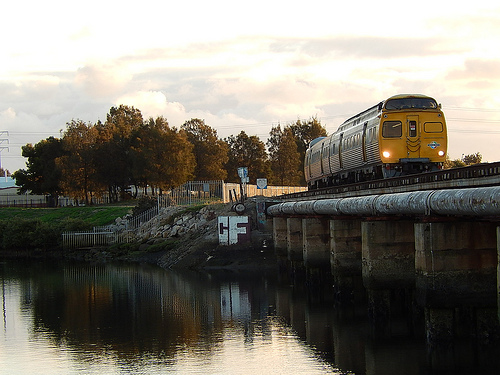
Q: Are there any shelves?
A: No, there are no shelves.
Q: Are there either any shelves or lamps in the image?
A: No, there are no shelves or lamps.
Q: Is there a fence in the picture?
A: Yes, there is a fence.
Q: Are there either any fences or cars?
A: Yes, there is a fence.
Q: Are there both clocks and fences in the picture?
A: No, there is a fence but no clocks.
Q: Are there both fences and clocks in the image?
A: No, there is a fence but no clocks.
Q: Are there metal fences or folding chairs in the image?
A: Yes, there is a metal fence.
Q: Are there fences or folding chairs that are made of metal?
A: Yes, the fence is made of metal.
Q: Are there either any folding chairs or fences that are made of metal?
A: Yes, the fence is made of metal.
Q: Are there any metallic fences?
A: Yes, there is a metal fence.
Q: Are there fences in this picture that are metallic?
A: Yes, there is a fence that is metallic.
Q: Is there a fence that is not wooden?
A: Yes, there is a metallic fence.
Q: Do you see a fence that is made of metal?
A: Yes, there is a fence that is made of metal.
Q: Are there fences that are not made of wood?
A: Yes, there is a fence that is made of metal.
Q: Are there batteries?
A: No, there are no batteries.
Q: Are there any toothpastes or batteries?
A: No, there are no batteries or toothpastes.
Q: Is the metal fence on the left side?
A: Yes, the fence is on the left of the image.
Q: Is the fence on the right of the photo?
A: No, the fence is on the left of the image.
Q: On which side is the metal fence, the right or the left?
A: The fence is on the left of the image.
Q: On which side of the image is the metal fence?
A: The fence is on the left of the image.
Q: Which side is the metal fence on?
A: The fence is on the left of the image.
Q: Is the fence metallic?
A: Yes, the fence is metallic.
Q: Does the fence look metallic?
A: Yes, the fence is metallic.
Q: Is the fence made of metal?
A: Yes, the fence is made of metal.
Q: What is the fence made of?
A: The fence is made of metal.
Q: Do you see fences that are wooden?
A: No, there is a fence but it is metallic.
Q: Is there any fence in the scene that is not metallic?
A: No, there is a fence but it is metallic.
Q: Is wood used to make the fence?
A: No, the fence is made of metal.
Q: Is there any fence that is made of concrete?
A: No, there is a fence but it is made of metal.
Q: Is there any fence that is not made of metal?
A: No, there is a fence but it is made of metal.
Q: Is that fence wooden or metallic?
A: The fence is metallic.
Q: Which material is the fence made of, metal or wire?
A: The fence is made of metal.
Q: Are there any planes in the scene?
A: No, there are no planes.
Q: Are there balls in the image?
A: No, there are no balls.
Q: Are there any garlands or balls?
A: No, there are no balls or garlands.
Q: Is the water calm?
A: Yes, the water is calm.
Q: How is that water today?
A: The water is calm.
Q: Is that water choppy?
A: No, the water is calm.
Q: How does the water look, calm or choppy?
A: The water is calm.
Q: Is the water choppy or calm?
A: The water is calm.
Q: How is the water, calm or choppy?
A: The water is calm.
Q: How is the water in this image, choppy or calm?
A: The water is calm.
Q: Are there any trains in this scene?
A: Yes, there is a train.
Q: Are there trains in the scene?
A: Yes, there is a train.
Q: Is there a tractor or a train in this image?
A: Yes, there is a train.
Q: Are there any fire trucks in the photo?
A: No, there are no fire trucks.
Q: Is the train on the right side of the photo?
A: Yes, the train is on the right of the image.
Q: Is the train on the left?
A: No, the train is on the right of the image.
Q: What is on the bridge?
A: The train is on the bridge.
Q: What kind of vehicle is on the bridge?
A: The vehicle is a train.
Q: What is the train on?
A: The train is on the bridge.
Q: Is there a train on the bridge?
A: Yes, there is a train on the bridge.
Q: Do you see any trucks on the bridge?
A: No, there is a train on the bridge.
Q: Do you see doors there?
A: Yes, there is a door.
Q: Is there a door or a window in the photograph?
A: Yes, there is a door.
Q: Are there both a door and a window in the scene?
A: Yes, there are both a door and a window.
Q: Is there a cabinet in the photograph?
A: No, there are no cabinets.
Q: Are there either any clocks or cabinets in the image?
A: No, there are no cabinets or clocks.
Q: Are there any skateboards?
A: No, there are no skateboards.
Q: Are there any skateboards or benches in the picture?
A: No, there are no skateboards or benches.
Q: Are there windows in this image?
A: Yes, there is a window.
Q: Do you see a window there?
A: Yes, there is a window.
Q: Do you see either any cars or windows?
A: Yes, there is a window.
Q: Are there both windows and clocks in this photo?
A: No, there is a window but no clocks.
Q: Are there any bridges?
A: Yes, there is a bridge.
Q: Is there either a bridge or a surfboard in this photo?
A: Yes, there is a bridge.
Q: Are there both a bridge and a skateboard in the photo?
A: No, there is a bridge but no skateboards.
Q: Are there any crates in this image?
A: No, there are no crates.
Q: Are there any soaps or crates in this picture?
A: No, there are no crates or soaps.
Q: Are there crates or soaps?
A: No, there are no crates or soaps.